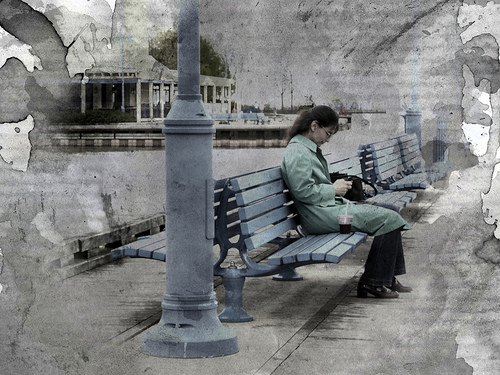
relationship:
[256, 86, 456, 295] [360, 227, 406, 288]
person wearing black pants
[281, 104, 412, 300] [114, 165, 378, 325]
person sitting on bench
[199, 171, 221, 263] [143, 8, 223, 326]
panel on pole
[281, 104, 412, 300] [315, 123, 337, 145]
person wearing eyeglasses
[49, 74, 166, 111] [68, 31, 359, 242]
pillars on building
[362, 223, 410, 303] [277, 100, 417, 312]
black pants on woman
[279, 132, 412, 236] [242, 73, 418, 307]
coat on woman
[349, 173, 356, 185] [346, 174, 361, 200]
straw in cup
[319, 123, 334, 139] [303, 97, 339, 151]
eyeglasses on face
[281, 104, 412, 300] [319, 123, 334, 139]
person possesses eyeglasses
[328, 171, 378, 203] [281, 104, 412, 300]
bag next to person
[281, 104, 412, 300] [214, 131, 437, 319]
person seated bench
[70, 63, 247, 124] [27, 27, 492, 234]
building in background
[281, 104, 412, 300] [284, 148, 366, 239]
person wears coat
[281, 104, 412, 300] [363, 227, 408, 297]
person wears black pants